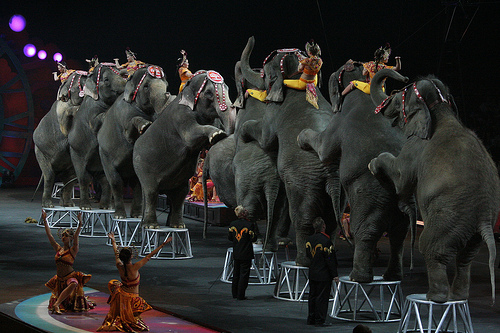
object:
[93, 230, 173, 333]
female performer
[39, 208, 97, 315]
female performer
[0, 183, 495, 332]
floor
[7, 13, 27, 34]
purple light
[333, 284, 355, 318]
beams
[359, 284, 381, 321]
beams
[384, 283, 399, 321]
beams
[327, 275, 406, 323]
structure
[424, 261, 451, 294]
leg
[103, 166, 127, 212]
leg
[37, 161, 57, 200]
leg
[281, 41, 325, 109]
woman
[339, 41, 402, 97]
woman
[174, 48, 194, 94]
woman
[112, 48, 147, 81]
woman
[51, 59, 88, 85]
woman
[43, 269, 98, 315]
skirt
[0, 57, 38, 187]
archway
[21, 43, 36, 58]
purple lights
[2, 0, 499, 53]
ceiling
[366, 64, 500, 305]
elephant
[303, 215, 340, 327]
male performers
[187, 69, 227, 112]
headdress